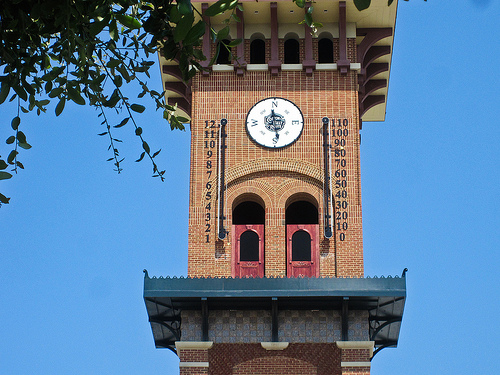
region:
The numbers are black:
[335, 219, 352, 232]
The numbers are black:
[335, 206, 350, 223]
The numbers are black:
[333, 196, 353, 214]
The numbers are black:
[332, 175, 350, 190]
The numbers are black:
[326, 163, 352, 182]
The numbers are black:
[332, 153, 348, 169]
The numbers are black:
[330, 148, 350, 160]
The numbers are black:
[330, 136, 352, 151]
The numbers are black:
[326, 123, 357, 142]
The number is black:
[200, 230, 215, 245]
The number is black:
[199, 222, 219, 234]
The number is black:
[203, 190, 218, 199]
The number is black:
[203, 177, 214, 193]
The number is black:
[204, 167, 216, 184]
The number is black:
[201, 155, 213, 172]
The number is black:
[202, 147, 217, 160]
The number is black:
[200, 138, 216, 151]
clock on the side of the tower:
[238, 90, 308, 152]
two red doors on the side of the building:
[228, 214, 326, 276]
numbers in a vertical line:
[201, 114, 216, 249]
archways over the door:
[216, 181, 333, 228]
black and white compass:
[241, 95, 311, 151]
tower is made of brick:
[129, 12, 416, 374]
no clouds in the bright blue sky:
[1, 2, 499, 374]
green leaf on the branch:
[121, 102, 148, 114]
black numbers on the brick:
[325, 119, 356, 254]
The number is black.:
[328, 113, 349, 128]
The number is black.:
[330, 125, 351, 140]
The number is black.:
[333, 135, 349, 148]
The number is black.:
[328, 145, 345, 160]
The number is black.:
[330, 155, 350, 166]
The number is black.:
[331, 176, 347, 188]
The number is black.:
[331, 165, 354, 180]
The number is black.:
[331, 188, 349, 200]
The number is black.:
[333, 199, 352, 211]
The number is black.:
[331, 208, 351, 223]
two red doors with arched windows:
[230, 222, 322, 274]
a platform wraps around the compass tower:
[137, 263, 407, 348]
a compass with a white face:
[246, 96, 298, 142]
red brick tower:
[171, 64, 378, 374]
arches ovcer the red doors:
[225, 181, 320, 223]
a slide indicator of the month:
[201, 115, 230, 245]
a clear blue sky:
[3, 0, 496, 374]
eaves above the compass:
[156, 2, 388, 122]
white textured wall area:
[169, 311, 371, 346]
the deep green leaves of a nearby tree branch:
[2, 4, 176, 186]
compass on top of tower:
[234, 83, 309, 153]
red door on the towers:
[224, 205, 274, 282]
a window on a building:
[240, 221, 262, 261]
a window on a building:
[282, 197, 318, 231]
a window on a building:
[228, 186, 264, 223]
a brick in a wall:
[202, 90, 216, 97]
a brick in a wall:
[236, 90, 252, 98]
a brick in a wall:
[287, 93, 301, 101]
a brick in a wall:
[250, 181, 260, 189]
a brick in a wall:
[310, 95, 320, 100]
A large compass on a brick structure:
[245, 95, 303, 150]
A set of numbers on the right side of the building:
[327, 110, 348, 240]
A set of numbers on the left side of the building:
[202, 118, 217, 245]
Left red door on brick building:
[233, 223, 264, 278]